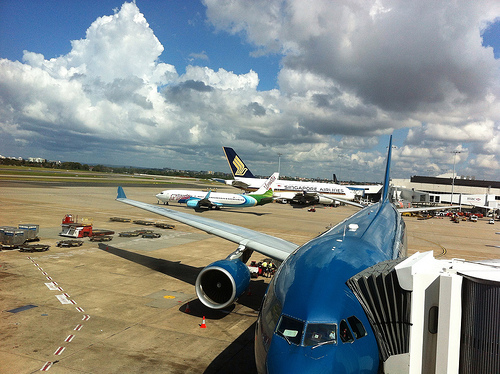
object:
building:
[386, 174, 500, 212]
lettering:
[339, 187, 346, 192]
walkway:
[395, 197, 490, 217]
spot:
[160, 293, 178, 302]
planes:
[155, 169, 279, 212]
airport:
[0, 164, 498, 374]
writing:
[282, 182, 347, 193]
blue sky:
[166, 18, 205, 48]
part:
[0, 2, 62, 45]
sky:
[0, 0, 499, 183]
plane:
[216, 145, 368, 210]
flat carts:
[55, 238, 84, 248]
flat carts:
[19, 242, 51, 253]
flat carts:
[153, 221, 175, 230]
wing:
[113, 183, 298, 266]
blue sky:
[3, 2, 67, 46]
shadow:
[95, 240, 287, 372]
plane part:
[219, 145, 257, 178]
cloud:
[0, 0, 499, 183]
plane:
[113, 134, 500, 373]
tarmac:
[0, 183, 499, 373]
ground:
[0, 163, 499, 373]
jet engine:
[193, 257, 251, 311]